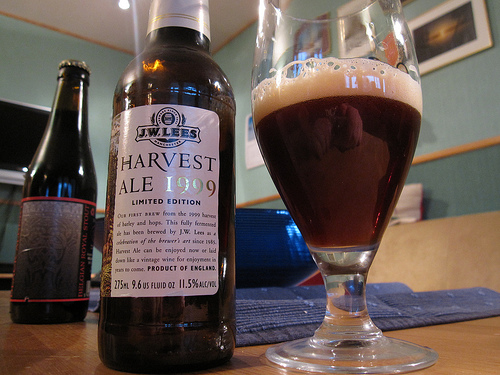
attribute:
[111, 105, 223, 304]
label — white, gold, black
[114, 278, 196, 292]
numbers — black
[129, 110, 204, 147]
logo — white, black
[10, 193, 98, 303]
label — black, red, gray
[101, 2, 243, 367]
bottle — glass, brown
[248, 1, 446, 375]
wine glass — full, large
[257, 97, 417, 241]
liquid — brown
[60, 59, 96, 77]
top — silver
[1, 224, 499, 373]
table — wooden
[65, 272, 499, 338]
placemat — blue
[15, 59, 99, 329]
bottle — brown, glass, dark brown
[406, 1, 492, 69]
photo — framed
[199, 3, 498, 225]
wall — green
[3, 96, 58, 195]
screen — black, silver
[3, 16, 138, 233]
wall — green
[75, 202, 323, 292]
bowl — dark blue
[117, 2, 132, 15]
light — white, bright, small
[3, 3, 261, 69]
ceiling — white